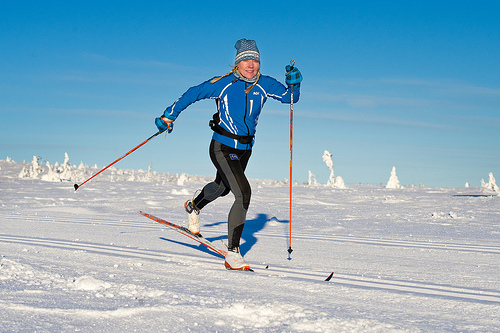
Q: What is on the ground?
A: Snow.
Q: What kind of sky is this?
A: Clear.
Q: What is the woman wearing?
A: Jacket.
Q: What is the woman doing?
A: Skiing.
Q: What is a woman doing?
A: Skiing.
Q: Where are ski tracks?
A: On the snow.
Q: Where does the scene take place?
A: On a ski slope.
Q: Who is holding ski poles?
A: The skier.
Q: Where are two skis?
A: Under woman's feet.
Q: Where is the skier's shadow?
A: On the snow.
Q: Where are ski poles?
A: In woman's hands.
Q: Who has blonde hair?
A: The woman.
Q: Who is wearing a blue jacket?
A: The skier.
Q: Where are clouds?
A: In the sky.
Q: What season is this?
A: Winter.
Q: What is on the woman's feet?
A: Skis.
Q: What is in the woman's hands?
A: Ski Poles.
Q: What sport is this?
A: Cross country skiing.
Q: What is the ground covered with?
A: Snow.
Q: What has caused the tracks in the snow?
A: Skis.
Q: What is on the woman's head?
A: Hat.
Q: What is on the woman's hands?
A: Gloves.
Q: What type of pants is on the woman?
A: Snowpants.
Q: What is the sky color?
A: Blue.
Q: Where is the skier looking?
A: At the camera.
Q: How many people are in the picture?
A: 1.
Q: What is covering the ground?
A: Snow.